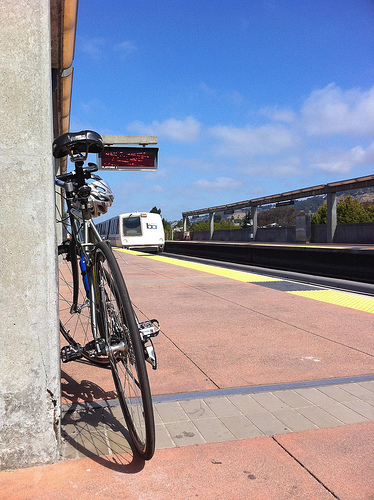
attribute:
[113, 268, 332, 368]
ground — red, stone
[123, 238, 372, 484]
platform — brick, red, brown, yellow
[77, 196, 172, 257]
train — white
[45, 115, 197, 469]
bike — blue, large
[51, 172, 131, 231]
helmet — silver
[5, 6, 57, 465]
wall — cement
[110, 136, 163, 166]
sign — red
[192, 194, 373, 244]
trees — green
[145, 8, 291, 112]
sky — blue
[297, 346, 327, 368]
stain — white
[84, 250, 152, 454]
tires — black, thin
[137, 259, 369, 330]
stripe — yellow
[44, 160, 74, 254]
post — cement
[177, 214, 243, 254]
bushes — green